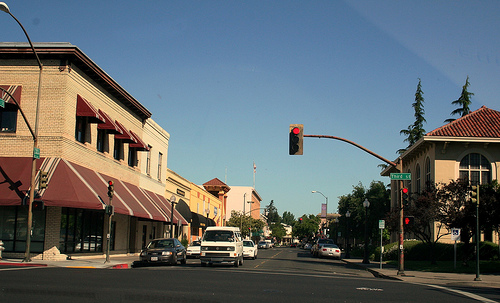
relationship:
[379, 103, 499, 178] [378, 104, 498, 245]
roof on building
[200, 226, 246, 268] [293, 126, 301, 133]
cars waiting at a light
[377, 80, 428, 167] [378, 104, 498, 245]
tree behind building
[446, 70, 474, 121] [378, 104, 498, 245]
tree behind building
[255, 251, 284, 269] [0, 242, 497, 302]
lines on street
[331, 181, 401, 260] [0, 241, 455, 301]
trees besides street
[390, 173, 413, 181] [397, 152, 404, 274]
green sign on pole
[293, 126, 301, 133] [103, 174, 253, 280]
light hanging over cars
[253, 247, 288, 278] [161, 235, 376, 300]
lines in center of street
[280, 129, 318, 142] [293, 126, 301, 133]
light on light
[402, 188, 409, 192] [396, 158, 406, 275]
red light on pole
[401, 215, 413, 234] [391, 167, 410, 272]
signal on pole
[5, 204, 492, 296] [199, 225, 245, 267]
foreground of van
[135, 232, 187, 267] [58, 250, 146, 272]
car parked at curb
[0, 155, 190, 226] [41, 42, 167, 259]
brown awning on building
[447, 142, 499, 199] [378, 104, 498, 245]
window on building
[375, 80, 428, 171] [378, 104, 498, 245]
tree behind building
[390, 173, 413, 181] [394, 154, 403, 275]
green sign on pole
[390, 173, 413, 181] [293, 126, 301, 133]
green sign on light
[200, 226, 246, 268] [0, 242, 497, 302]
cars on street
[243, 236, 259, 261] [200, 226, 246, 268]
car behind cars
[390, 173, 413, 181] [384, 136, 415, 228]
green sign sign in foreground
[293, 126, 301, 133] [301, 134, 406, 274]
light on a pole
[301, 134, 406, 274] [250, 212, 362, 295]
pole over a street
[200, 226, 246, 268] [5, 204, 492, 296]
cars in foreground